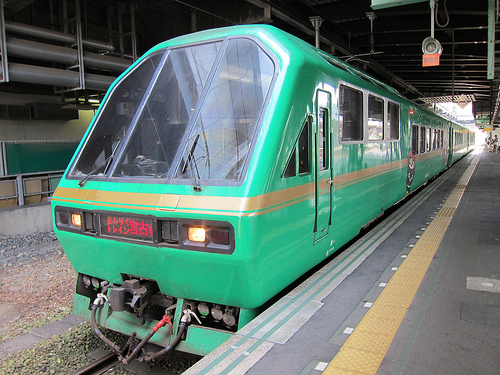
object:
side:
[258, 69, 410, 304]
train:
[49, 22, 476, 353]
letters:
[106, 215, 154, 239]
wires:
[90, 289, 201, 365]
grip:
[152, 315, 175, 335]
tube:
[122, 327, 155, 364]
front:
[50, 20, 304, 364]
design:
[405, 151, 417, 192]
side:
[376, 105, 445, 195]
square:
[315, 359, 329, 372]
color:
[243, 315, 289, 350]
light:
[185, 227, 206, 243]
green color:
[250, 225, 308, 269]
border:
[49, 157, 399, 219]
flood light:
[420, 38, 441, 55]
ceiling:
[394, 11, 484, 79]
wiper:
[179, 135, 199, 191]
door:
[311, 85, 336, 246]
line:
[324, 295, 411, 375]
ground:
[184, 222, 485, 372]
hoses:
[123, 303, 201, 371]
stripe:
[285, 304, 303, 337]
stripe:
[260, 293, 282, 327]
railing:
[0, 171, 63, 204]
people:
[486, 131, 497, 152]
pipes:
[2, 23, 136, 93]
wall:
[6, 5, 378, 210]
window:
[332, 82, 366, 142]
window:
[364, 88, 388, 139]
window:
[384, 98, 403, 144]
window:
[410, 122, 420, 160]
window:
[418, 119, 430, 154]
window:
[423, 124, 436, 157]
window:
[434, 126, 441, 148]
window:
[440, 126, 450, 149]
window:
[63, 41, 264, 191]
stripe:
[60, 144, 477, 218]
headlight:
[69, 213, 81, 226]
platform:
[184, 138, 499, 371]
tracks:
[77, 334, 145, 373]